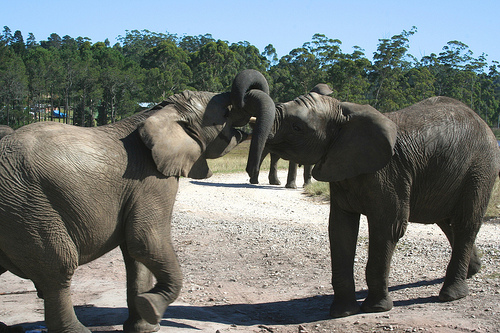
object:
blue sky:
[1, 0, 498, 88]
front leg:
[366, 204, 408, 306]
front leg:
[327, 206, 360, 311]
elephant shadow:
[191, 295, 331, 332]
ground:
[220, 257, 323, 292]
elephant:
[1, 87, 276, 330]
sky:
[0, 11, 497, 65]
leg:
[251, 152, 263, 189]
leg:
[268, 145, 281, 191]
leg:
[286, 156, 299, 190]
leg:
[307, 166, 311, 193]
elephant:
[256, 57, 496, 324]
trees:
[35, 12, 499, 139]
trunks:
[221, 62, 288, 194]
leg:
[129, 226, 194, 323]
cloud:
[0, 0, 500, 35]